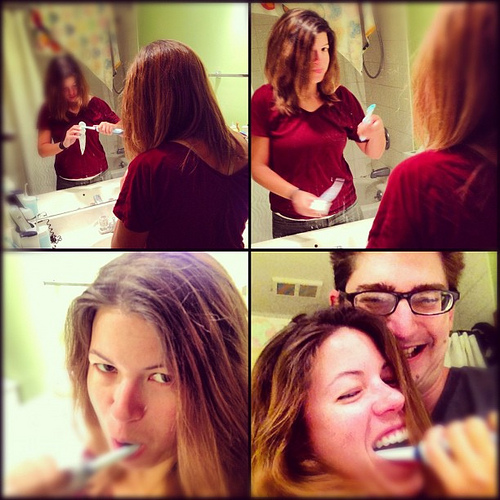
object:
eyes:
[93, 360, 118, 377]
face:
[82, 307, 178, 464]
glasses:
[338, 287, 461, 317]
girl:
[107, 38, 248, 248]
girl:
[367, 0, 500, 251]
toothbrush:
[46, 438, 143, 485]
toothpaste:
[307, 173, 347, 213]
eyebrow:
[353, 280, 397, 296]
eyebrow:
[408, 282, 449, 293]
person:
[251, 7, 388, 248]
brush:
[59, 443, 141, 492]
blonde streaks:
[269, 373, 299, 420]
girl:
[251, 5, 388, 242]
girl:
[255, 311, 437, 498]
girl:
[1, 252, 249, 500]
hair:
[62, 251, 250, 500]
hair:
[264, 4, 340, 116]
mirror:
[1, 4, 130, 197]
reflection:
[29, 45, 124, 182]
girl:
[32, 45, 120, 192]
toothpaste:
[77, 120, 89, 156]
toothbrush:
[81, 123, 124, 137]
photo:
[116, 45, 396, 423]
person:
[0, 249, 251, 500]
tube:
[77, 117, 87, 157]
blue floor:
[414, 447, 425, 463]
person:
[33, 48, 118, 193]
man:
[319, 247, 468, 392]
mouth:
[366, 421, 432, 465]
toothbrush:
[376, 431, 435, 461]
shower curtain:
[2, 7, 60, 195]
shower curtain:
[440, 329, 488, 369]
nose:
[370, 376, 406, 417]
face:
[295, 326, 426, 496]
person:
[326, 250, 496, 428]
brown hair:
[117, 37, 252, 175]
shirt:
[109, 140, 249, 249]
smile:
[395, 338, 430, 361]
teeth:
[385, 424, 413, 444]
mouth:
[106, 436, 146, 462]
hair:
[252, 303, 438, 495]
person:
[248, 293, 500, 500]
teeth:
[66, 91, 76, 97]